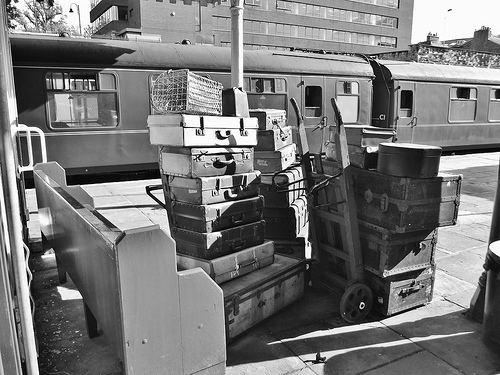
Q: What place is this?
A: It is a sidewalk.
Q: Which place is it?
A: It is a sidewalk.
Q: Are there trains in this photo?
A: Yes, there is a train.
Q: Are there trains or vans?
A: Yes, there is a train.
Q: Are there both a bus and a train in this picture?
A: No, there is a train but no buses.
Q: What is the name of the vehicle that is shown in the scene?
A: The vehicle is a train.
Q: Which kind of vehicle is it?
A: The vehicle is a train.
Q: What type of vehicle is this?
A: This is a train.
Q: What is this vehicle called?
A: This is a train.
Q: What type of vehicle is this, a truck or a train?
A: This is a train.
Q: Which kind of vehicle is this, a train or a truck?
A: This is a train.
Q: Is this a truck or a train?
A: This is a train.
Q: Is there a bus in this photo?
A: No, there are no buses.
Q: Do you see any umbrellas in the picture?
A: No, there are no umbrellas.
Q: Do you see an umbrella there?
A: No, there are no umbrellas.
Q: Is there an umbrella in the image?
A: No, there are no umbrellas.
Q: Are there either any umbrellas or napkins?
A: No, there are no umbrellas or napkins.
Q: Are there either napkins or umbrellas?
A: No, there are no umbrellas or napkins.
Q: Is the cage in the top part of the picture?
A: Yes, the cage is in the top of the image.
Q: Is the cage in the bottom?
A: No, the cage is in the top of the image.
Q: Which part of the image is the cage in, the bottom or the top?
A: The cage is in the top of the image.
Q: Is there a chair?
A: No, there are no chairs.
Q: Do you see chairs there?
A: No, there are no chairs.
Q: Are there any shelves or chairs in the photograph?
A: No, there are no chairs or shelves.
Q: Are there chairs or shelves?
A: No, there are no chairs or shelves.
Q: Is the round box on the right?
A: Yes, the box is on the right of the image.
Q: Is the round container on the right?
A: Yes, the box is on the right of the image.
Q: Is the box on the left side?
A: No, the box is on the right of the image.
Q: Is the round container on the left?
A: No, the box is on the right of the image.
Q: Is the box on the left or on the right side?
A: The box is on the right of the image.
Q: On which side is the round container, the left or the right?
A: The box is on the right of the image.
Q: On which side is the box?
A: The box is on the right of the image.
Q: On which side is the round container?
A: The box is on the right of the image.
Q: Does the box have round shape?
A: Yes, the box is round.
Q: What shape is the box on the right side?
A: The box is round.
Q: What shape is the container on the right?
A: The box is round.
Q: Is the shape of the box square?
A: No, the box is round.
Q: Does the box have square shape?
A: No, the box is round.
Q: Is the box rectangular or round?
A: The box is round.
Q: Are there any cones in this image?
A: No, there are no cones.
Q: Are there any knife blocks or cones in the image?
A: No, there are no cones or knife blocks.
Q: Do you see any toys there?
A: No, there are no toys.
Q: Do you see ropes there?
A: No, there are no ropes.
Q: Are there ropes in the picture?
A: No, there are no ropes.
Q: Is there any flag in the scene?
A: No, there are no flags.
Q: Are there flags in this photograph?
A: No, there are no flags.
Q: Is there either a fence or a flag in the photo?
A: No, there are no flags or fences.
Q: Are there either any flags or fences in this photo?
A: No, there are no flags or fences.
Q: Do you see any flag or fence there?
A: No, there are no flags or fences.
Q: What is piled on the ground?
A: The luggage is piled on the ground.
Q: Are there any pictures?
A: No, there are no pictures.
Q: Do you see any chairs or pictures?
A: No, there are no pictures or chairs.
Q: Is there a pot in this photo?
A: No, there are no pots.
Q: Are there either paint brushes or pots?
A: No, there are no pots or paint brushes.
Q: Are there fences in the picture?
A: No, there are no fences.